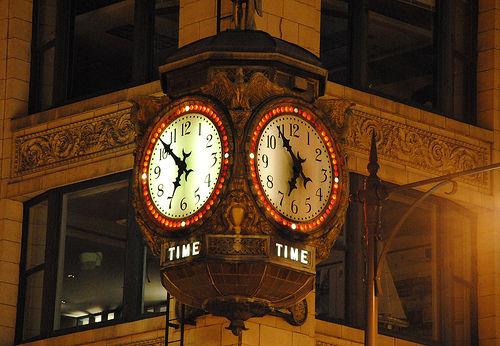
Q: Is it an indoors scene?
A: Yes, it is indoors.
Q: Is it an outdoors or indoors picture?
A: It is indoors.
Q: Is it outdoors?
A: No, it is indoors.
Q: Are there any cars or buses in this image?
A: No, there are no cars or buses.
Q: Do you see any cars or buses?
A: No, there are no cars or buses.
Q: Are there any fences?
A: No, there are no fences.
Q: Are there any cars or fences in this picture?
A: No, there are no fences or cars.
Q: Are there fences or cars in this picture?
A: No, there are no fences or cars.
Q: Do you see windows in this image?
A: Yes, there is a window.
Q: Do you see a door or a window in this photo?
A: Yes, there is a window.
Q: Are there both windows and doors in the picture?
A: No, there is a window but no doors.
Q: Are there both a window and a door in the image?
A: No, there is a window but no doors.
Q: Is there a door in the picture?
A: No, there are no doors.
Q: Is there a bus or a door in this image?
A: No, there are no doors or buses.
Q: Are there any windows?
A: Yes, there is a window.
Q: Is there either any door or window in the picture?
A: Yes, there is a window.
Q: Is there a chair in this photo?
A: No, there are no chairs.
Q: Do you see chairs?
A: No, there are no chairs.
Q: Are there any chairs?
A: No, there are no chairs.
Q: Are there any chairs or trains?
A: No, there are no chairs or trains.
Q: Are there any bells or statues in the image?
A: No, there are no statues or bells.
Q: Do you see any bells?
A: No, there are no bells.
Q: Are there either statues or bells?
A: No, there are no bells or statues.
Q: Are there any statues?
A: No, there are no statues.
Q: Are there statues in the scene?
A: No, there are no statues.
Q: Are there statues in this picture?
A: No, there are no statues.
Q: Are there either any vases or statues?
A: No, there are no statues or vases.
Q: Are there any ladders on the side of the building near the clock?
A: Yes, there is a ladder on the side of the building.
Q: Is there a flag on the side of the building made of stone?
A: No, there is a ladder on the side of the building.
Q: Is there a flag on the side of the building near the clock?
A: No, there is a ladder on the side of the building.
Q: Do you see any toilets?
A: No, there are no toilets.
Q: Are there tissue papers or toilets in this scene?
A: No, there are no toilets or tissue papers.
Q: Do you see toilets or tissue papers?
A: No, there are no toilets or tissue papers.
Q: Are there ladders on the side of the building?
A: Yes, there is a ladder on the side of the building.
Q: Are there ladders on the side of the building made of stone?
A: Yes, there is a ladder on the side of the building.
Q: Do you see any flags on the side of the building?
A: No, there is a ladder on the side of the building.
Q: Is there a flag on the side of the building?
A: No, there is a ladder on the side of the building.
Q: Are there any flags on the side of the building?
A: No, there is a ladder on the side of the building.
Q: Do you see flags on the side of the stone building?
A: No, there is a ladder on the side of the building.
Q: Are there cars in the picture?
A: No, there are no cars.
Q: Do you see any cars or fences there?
A: No, there are no cars or fences.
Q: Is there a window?
A: Yes, there is a window.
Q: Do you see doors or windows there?
A: Yes, there is a window.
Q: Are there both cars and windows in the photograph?
A: No, there is a window but no cars.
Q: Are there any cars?
A: No, there are no cars.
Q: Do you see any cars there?
A: No, there are no cars.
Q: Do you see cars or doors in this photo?
A: No, there are no cars or doors.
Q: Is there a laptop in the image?
A: No, there are no laptops.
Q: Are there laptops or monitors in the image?
A: No, there are no laptops or monitors.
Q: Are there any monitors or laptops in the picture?
A: No, there are no laptops or monitors.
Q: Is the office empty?
A: Yes, the office is empty.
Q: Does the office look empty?
A: Yes, the office is empty.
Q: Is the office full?
A: No, the office is empty.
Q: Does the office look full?
A: No, the office is empty.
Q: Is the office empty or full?
A: The office is empty.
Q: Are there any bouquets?
A: No, there are no bouquets.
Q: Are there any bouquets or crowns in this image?
A: No, there are no bouquets or crowns.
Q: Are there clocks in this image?
A: Yes, there is a clock.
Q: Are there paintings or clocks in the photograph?
A: Yes, there is a clock.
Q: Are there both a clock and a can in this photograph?
A: No, there is a clock but no cans.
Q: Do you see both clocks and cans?
A: No, there is a clock but no cans.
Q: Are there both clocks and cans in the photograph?
A: No, there is a clock but no cans.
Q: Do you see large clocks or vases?
A: Yes, there is a large clock.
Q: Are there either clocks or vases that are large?
A: Yes, the clock is large.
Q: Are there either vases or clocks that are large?
A: Yes, the clock is large.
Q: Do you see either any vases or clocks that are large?
A: Yes, the clock is large.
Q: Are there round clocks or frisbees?
A: Yes, there is a round clock.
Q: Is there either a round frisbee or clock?
A: Yes, there is a round clock.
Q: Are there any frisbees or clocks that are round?
A: Yes, the clock is round.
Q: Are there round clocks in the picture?
A: Yes, there is a round clock.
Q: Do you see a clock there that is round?
A: Yes, there is a clock that is round.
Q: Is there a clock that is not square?
A: Yes, there is a round clock.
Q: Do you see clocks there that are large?
A: Yes, there is a large clock.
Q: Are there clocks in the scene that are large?
A: Yes, there is a clock that is large.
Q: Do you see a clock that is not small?
A: Yes, there is a large clock.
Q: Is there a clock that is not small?
A: Yes, there is a large clock.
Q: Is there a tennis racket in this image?
A: No, there are no rackets.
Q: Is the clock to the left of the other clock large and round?
A: Yes, the clock is large and round.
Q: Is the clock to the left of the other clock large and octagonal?
A: No, the clock is large but round.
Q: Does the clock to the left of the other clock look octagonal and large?
A: No, the clock is large but round.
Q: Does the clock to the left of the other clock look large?
A: Yes, the clock is large.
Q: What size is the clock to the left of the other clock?
A: The clock is large.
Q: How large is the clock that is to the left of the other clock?
A: The clock is large.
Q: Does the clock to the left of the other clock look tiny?
A: No, the clock is large.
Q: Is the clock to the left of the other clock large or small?
A: The clock is large.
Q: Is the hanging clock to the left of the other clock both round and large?
A: Yes, the clock is round and large.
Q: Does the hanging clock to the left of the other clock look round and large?
A: Yes, the clock is round and large.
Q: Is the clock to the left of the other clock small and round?
A: No, the clock is round but large.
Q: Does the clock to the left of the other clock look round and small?
A: No, the clock is round but large.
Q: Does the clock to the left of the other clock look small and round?
A: No, the clock is round but large.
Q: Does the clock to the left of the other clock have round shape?
A: Yes, the clock is round.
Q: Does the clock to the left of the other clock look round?
A: Yes, the clock is round.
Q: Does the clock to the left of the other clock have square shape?
A: No, the clock is round.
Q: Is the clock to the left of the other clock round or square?
A: The clock is round.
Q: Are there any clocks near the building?
A: Yes, there is a clock near the building.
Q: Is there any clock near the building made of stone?
A: Yes, there is a clock near the building.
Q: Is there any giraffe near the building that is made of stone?
A: No, there is a clock near the building.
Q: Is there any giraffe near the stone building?
A: No, there is a clock near the building.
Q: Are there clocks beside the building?
A: Yes, there is a clock beside the building.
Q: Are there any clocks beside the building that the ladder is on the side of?
A: Yes, there is a clock beside the building.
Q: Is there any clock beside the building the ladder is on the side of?
A: Yes, there is a clock beside the building.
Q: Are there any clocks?
A: Yes, there is a clock.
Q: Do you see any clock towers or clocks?
A: Yes, there is a clock.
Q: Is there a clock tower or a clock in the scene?
A: Yes, there is a clock.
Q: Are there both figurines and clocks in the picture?
A: No, there is a clock but no figurines.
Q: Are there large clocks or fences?
A: Yes, there is a large clock.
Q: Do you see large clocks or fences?
A: Yes, there is a large clock.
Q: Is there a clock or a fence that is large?
A: Yes, the clock is large.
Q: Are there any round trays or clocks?
A: Yes, there is a round clock.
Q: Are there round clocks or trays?
A: Yes, there is a round clock.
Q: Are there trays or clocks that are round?
A: Yes, the clock is round.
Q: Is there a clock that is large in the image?
A: Yes, there is a large clock.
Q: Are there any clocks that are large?
A: Yes, there is a clock that is large.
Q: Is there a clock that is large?
A: Yes, there is a clock that is large.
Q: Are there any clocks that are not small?
A: Yes, there is a large clock.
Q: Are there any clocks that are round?
A: Yes, there is a round clock.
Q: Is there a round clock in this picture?
A: Yes, there is a round clock.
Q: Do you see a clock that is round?
A: Yes, there is a round clock.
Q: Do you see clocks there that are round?
A: Yes, there is a round clock.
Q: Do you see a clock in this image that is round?
A: Yes, there is a clock that is round.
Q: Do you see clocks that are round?
A: Yes, there is a clock that is round.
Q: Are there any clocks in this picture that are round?
A: Yes, there is a clock that is round.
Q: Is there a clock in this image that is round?
A: Yes, there is a clock that is round.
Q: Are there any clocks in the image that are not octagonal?
A: Yes, there is an round clock.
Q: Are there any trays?
A: No, there are no trays.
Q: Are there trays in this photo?
A: No, there are no trays.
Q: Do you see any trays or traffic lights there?
A: No, there are no trays or traffic lights.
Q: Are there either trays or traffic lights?
A: No, there are no trays or traffic lights.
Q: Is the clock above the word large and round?
A: Yes, the clock is large and round.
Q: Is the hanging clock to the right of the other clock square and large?
A: No, the clock is large but round.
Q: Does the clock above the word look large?
A: Yes, the clock is large.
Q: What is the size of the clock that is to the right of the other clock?
A: The clock is large.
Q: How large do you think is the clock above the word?
A: The clock is large.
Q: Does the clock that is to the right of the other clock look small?
A: No, the clock is large.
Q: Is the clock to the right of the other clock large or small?
A: The clock is large.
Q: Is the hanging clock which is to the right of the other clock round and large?
A: Yes, the clock is round and large.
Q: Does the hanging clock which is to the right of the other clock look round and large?
A: Yes, the clock is round and large.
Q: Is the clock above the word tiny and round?
A: No, the clock is round but large.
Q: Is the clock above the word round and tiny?
A: No, the clock is round but large.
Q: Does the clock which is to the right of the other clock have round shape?
A: Yes, the clock is round.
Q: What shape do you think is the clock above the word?
A: The clock is round.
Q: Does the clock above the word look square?
A: No, the clock is round.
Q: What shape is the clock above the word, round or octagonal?
A: The clock is round.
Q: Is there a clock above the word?
A: Yes, there is a clock above the word.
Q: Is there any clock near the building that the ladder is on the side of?
A: Yes, there is a clock near the building.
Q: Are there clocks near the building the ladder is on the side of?
A: Yes, there is a clock near the building.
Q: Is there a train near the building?
A: No, there is a clock near the building.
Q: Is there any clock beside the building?
A: Yes, there is a clock beside the building.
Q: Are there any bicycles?
A: No, there are no bicycles.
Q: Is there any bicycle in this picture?
A: No, there are no bicycles.